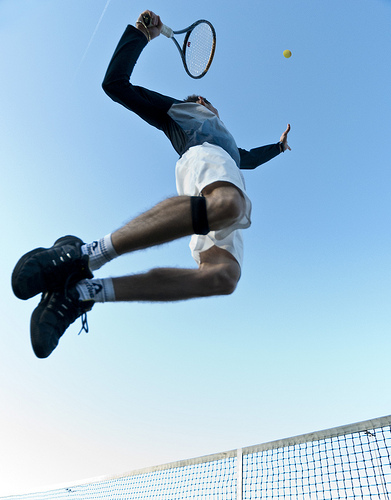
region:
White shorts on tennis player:
[144, 151, 273, 257]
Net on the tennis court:
[235, 411, 304, 485]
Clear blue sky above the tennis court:
[165, 372, 242, 427]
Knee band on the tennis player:
[175, 179, 206, 234]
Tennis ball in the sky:
[267, 40, 381, 131]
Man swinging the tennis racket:
[132, 6, 273, 56]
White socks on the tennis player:
[61, 235, 119, 356]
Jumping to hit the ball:
[62, 18, 316, 352]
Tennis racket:
[123, 7, 291, 110]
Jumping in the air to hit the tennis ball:
[38, 208, 265, 367]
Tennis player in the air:
[37, 37, 314, 303]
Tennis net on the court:
[243, 413, 309, 494]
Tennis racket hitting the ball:
[137, 10, 385, 75]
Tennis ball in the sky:
[276, 15, 303, 79]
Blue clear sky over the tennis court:
[286, 182, 388, 284]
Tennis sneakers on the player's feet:
[16, 216, 111, 373]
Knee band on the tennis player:
[179, 172, 231, 258]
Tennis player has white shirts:
[163, 137, 230, 180]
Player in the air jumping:
[28, 79, 251, 323]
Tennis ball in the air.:
[279, 47, 294, 60]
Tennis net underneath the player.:
[3, 410, 388, 497]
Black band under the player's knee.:
[191, 192, 211, 239]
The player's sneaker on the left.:
[8, 230, 98, 295]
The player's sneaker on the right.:
[22, 276, 103, 355]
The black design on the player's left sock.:
[85, 237, 98, 255]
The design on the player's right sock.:
[81, 276, 103, 297]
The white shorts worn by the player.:
[180, 141, 255, 273]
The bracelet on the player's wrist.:
[136, 13, 155, 43]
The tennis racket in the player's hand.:
[168, 9, 216, 81]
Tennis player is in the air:
[15, 7, 295, 365]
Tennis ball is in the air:
[279, 49, 294, 59]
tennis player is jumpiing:
[12, 10, 291, 356]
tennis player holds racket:
[133, 10, 220, 79]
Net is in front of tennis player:
[14, 416, 389, 498]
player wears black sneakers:
[11, 232, 95, 357]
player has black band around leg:
[188, 194, 213, 236]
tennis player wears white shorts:
[168, 144, 253, 274]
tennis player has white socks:
[77, 232, 118, 301]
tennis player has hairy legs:
[102, 180, 240, 317]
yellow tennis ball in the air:
[278, 43, 299, 63]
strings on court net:
[286, 452, 353, 481]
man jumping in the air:
[26, 37, 287, 350]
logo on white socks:
[81, 280, 107, 299]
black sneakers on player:
[18, 229, 92, 360]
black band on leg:
[182, 196, 218, 239]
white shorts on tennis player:
[169, 144, 252, 275]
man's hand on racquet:
[137, 6, 223, 83]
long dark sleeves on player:
[97, 23, 151, 115]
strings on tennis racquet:
[191, 34, 211, 61]